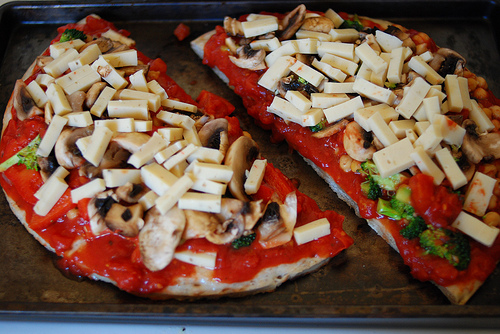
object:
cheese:
[293, 217, 333, 244]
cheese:
[177, 191, 224, 213]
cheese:
[31, 111, 70, 159]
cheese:
[81, 127, 113, 168]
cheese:
[107, 97, 152, 119]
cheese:
[464, 166, 496, 216]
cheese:
[370, 134, 416, 179]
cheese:
[322, 94, 365, 122]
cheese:
[354, 39, 387, 73]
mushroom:
[98, 200, 147, 236]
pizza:
[0, 12, 351, 302]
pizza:
[190, 7, 500, 308]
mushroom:
[462, 118, 499, 162]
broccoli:
[57, 26, 84, 46]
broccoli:
[21, 141, 42, 171]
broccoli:
[232, 232, 257, 252]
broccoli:
[419, 224, 474, 272]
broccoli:
[404, 212, 426, 240]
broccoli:
[360, 157, 405, 197]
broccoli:
[291, 74, 306, 95]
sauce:
[0, 121, 346, 295]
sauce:
[231, 1, 500, 279]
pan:
[3, 3, 500, 303]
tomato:
[169, 22, 193, 43]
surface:
[1, 321, 500, 334]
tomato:
[29, 187, 73, 229]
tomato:
[410, 173, 459, 226]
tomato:
[6, 159, 43, 204]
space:
[104, 43, 403, 243]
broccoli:
[223, 46, 233, 53]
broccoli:
[339, 11, 365, 32]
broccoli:
[311, 118, 325, 135]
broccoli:
[375, 180, 419, 228]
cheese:
[244, 160, 271, 189]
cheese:
[71, 178, 111, 204]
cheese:
[45, 83, 72, 116]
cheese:
[452, 207, 496, 243]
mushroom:
[224, 130, 260, 203]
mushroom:
[12, 76, 43, 119]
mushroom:
[54, 126, 84, 165]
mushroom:
[198, 111, 230, 149]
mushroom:
[233, 46, 266, 67]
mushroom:
[434, 47, 466, 79]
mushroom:
[342, 125, 377, 158]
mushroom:
[279, 0, 306, 36]